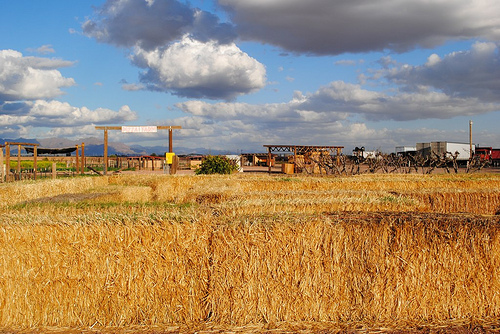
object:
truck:
[465, 118, 477, 165]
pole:
[17, 143, 23, 179]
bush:
[194, 153, 241, 175]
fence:
[294, 150, 494, 174]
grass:
[4, 159, 69, 173]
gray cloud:
[80, 0, 198, 52]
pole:
[167, 125, 177, 177]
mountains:
[0, 136, 134, 155]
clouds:
[122, 35, 269, 103]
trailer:
[470, 146, 500, 160]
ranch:
[429, 140, 477, 161]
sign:
[164, 151, 177, 167]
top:
[260, 143, 347, 151]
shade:
[240, 168, 285, 173]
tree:
[194, 155, 238, 176]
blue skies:
[0, 1, 500, 153]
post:
[268, 148, 273, 174]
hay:
[0, 212, 500, 327]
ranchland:
[0, 171, 500, 333]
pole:
[102, 128, 108, 174]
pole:
[79, 142, 87, 174]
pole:
[266, 147, 275, 174]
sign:
[120, 125, 160, 133]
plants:
[0, 197, 191, 207]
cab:
[473, 146, 500, 163]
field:
[0, 165, 500, 333]